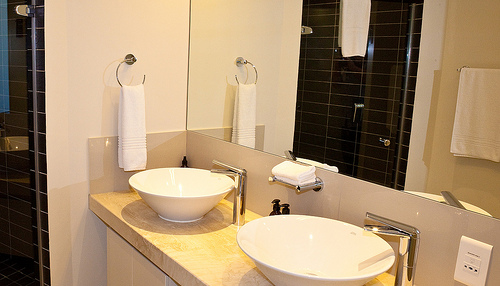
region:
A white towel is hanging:
[114, 78, 154, 174]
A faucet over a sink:
[234, 207, 422, 283]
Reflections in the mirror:
[185, 2, 498, 220]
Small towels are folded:
[268, 154, 320, 191]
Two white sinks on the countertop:
[124, 160, 401, 282]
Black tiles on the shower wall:
[1, 1, 50, 283]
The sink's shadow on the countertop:
[119, 197, 237, 238]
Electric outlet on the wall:
[450, 232, 494, 284]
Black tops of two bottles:
[265, 194, 294, 218]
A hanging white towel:
[446, 62, 499, 169]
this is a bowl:
[122, 152, 239, 236]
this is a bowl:
[224, 163, 391, 284]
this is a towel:
[94, 65, 154, 176]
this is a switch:
[440, 211, 495, 273]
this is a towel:
[451, 71, 496, 166]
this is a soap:
[264, 153, 318, 204]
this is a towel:
[222, 51, 269, 155]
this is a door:
[285, 6, 435, 188]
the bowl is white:
[242, 202, 400, 282]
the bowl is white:
[128, 153, 226, 223]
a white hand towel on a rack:
[116, 85, 147, 172]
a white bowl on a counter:
[128, 167, 234, 222]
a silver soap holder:
[268, 158, 321, 188]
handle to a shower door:
[378, 137, 390, 146]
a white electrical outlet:
[451, 233, 495, 284]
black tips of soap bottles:
[270, 198, 290, 215]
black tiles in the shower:
[293, 2, 423, 190]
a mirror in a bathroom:
[287, 0, 497, 219]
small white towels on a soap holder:
[272, 158, 316, 186]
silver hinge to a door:
[303, 24, 312, 37]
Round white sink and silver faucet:
[126, 157, 246, 234]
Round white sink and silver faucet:
[235, 208, 419, 284]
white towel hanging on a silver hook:
[113, 52, 149, 172]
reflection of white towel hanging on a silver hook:
[228, 55, 259, 154]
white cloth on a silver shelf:
[266, 159, 322, 194]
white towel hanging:
[447, 65, 499, 167]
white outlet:
[451, 236, 493, 284]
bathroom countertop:
[84, 188, 396, 284]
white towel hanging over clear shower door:
[289, 1, 419, 194]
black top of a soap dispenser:
[266, 198, 284, 218]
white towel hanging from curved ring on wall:
[40, 1, 185, 281]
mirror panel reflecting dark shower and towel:
[190, 0, 490, 210]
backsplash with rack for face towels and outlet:
[175, 130, 490, 280]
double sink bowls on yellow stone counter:
[95, 185, 410, 280]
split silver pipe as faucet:
[205, 155, 245, 225]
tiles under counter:
[100, 225, 165, 280]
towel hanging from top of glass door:
[335, 0, 370, 55]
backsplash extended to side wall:
[90, 126, 185, 191]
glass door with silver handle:
[295, 0, 425, 185]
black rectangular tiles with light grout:
[292, 1, 422, 186]